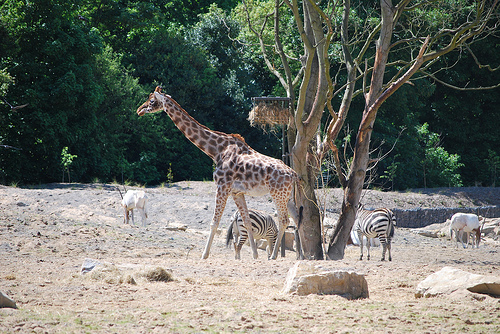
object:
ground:
[0, 183, 500, 334]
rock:
[280, 259, 369, 301]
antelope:
[448, 212, 483, 249]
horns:
[476, 206, 481, 216]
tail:
[225, 218, 237, 248]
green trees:
[0, 0, 177, 188]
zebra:
[225, 207, 282, 261]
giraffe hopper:
[248, 95, 295, 129]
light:
[0, 180, 500, 334]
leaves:
[146, 50, 154, 53]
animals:
[135, 85, 305, 261]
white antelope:
[114, 182, 150, 228]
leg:
[204, 167, 237, 254]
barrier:
[390, 205, 499, 228]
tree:
[221, 0, 500, 263]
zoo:
[0, 0, 500, 334]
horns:
[114, 187, 123, 199]